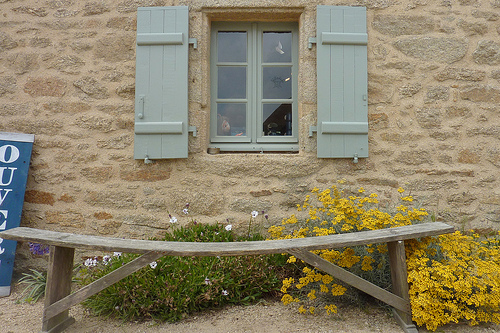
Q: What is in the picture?
A: A bench.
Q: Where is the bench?
A: On the ground.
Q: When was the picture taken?
A: Daytime.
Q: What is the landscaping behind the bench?
A: Flowers.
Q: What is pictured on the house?
A: A window.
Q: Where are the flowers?
A: Side of the house.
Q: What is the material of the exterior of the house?
A: Bricks.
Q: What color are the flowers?
A: Yellow and white.